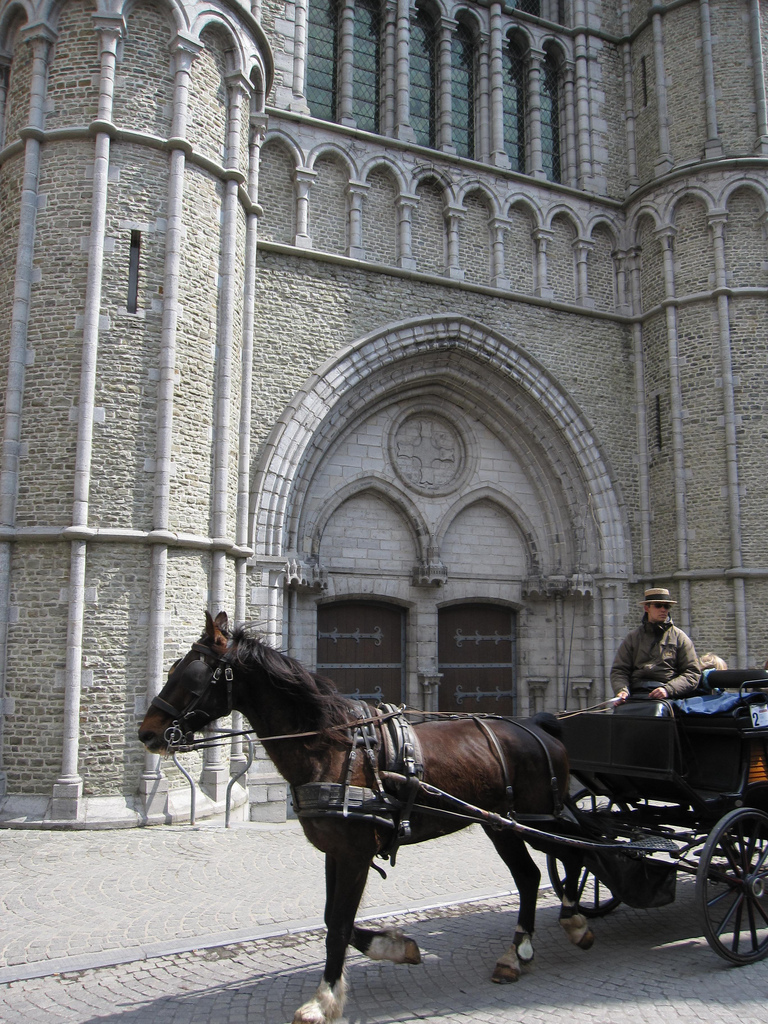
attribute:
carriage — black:
[551, 665, 766, 966]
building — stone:
[0, 5, 744, 834]